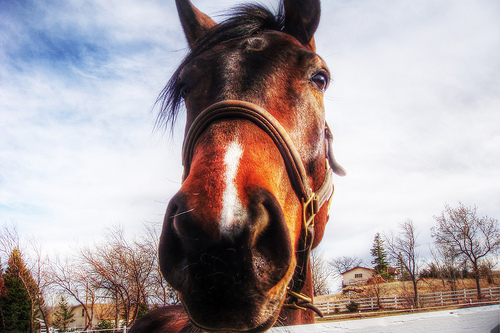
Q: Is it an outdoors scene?
A: Yes, it is outdoors.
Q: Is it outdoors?
A: Yes, it is outdoors.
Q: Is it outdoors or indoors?
A: It is outdoors.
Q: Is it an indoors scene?
A: No, it is outdoors.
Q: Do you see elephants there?
A: No, there are no elephants.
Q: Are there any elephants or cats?
A: No, there are no elephants or cats.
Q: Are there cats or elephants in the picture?
A: No, there are no elephants or cats.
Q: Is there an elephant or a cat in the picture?
A: No, there are no elephants or cats.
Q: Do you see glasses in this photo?
A: No, there are no glasses.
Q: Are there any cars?
A: No, there are no cars.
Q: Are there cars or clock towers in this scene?
A: No, there are no cars or clock towers.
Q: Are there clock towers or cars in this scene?
A: No, there are no cars or clock towers.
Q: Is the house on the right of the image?
A: Yes, the house is on the right of the image.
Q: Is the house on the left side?
A: No, the house is on the right of the image.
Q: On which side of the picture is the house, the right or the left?
A: The house is on the right of the image.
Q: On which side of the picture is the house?
A: The house is on the right of the image.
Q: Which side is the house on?
A: The house is on the right of the image.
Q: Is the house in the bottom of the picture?
A: Yes, the house is in the bottom of the image.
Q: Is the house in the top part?
A: No, the house is in the bottom of the image.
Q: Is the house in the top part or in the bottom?
A: The house is in the bottom of the image.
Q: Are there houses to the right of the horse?
A: Yes, there is a house to the right of the horse.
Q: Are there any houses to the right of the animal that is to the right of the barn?
A: Yes, there is a house to the right of the horse.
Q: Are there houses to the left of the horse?
A: No, the house is to the right of the horse.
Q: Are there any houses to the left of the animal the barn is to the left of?
A: No, the house is to the right of the horse.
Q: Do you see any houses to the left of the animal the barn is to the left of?
A: No, the house is to the right of the horse.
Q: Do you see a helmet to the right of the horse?
A: No, there is a house to the right of the horse.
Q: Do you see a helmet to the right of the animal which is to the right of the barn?
A: No, there is a house to the right of the horse.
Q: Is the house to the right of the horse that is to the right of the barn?
A: Yes, the house is to the right of the horse.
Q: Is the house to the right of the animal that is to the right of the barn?
A: Yes, the house is to the right of the horse.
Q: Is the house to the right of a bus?
A: No, the house is to the right of the horse.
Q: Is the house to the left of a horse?
A: No, the house is to the right of a horse.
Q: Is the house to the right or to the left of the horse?
A: The house is to the right of the horse.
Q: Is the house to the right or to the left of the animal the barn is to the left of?
A: The house is to the right of the horse.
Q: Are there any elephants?
A: No, there are no elephants.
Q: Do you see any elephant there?
A: No, there are no elephants.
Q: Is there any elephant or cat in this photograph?
A: No, there are no elephants or cats.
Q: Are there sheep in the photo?
A: No, there are no sheep.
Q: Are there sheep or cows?
A: No, there are no sheep or cows.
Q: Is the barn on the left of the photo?
A: Yes, the barn is on the left of the image.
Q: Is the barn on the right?
A: No, the barn is on the left of the image.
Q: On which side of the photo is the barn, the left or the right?
A: The barn is on the left of the image.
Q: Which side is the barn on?
A: The barn is on the left of the image.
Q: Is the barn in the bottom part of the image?
A: Yes, the barn is in the bottom of the image.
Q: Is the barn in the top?
A: No, the barn is in the bottom of the image.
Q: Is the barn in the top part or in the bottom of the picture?
A: The barn is in the bottom of the image.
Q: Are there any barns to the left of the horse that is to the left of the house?
A: Yes, there is a barn to the left of the horse.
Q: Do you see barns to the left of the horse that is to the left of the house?
A: Yes, there is a barn to the left of the horse.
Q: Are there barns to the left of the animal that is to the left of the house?
A: Yes, there is a barn to the left of the horse.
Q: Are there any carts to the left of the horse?
A: No, there is a barn to the left of the horse.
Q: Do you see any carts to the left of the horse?
A: No, there is a barn to the left of the horse.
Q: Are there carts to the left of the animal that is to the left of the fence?
A: No, there is a barn to the left of the horse.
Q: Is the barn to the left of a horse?
A: Yes, the barn is to the left of a horse.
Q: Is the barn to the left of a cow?
A: No, the barn is to the left of a horse.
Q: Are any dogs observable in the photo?
A: No, there are no dogs.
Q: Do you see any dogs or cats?
A: No, there are no dogs or cats.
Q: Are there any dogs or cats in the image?
A: No, there are no dogs or cats.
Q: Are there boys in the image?
A: No, there are no boys.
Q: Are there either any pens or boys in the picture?
A: No, there are no boys or pens.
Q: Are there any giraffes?
A: No, there are no giraffes.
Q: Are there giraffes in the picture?
A: No, there are no giraffes.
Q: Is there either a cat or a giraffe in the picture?
A: No, there are no giraffes or cats.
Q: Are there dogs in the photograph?
A: No, there are no dogs.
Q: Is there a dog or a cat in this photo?
A: No, there are no dogs or cats.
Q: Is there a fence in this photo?
A: Yes, there is a fence.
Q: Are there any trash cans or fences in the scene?
A: Yes, there is a fence.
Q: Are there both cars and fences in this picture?
A: No, there is a fence but no cars.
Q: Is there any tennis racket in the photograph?
A: No, there are no rackets.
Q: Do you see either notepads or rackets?
A: No, there are no rackets or notepads.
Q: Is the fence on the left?
A: No, the fence is on the right of the image.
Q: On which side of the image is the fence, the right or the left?
A: The fence is on the right of the image.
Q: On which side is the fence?
A: The fence is on the right of the image.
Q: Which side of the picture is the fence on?
A: The fence is on the right of the image.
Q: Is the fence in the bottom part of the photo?
A: Yes, the fence is in the bottom of the image.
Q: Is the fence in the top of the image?
A: No, the fence is in the bottom of the image.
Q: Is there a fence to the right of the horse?
A: Yes, there is a fence to the right of the horse.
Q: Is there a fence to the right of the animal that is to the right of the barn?
A: Yes, there is a fence to the right of the horse.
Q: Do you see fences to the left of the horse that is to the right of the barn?
A: No, the fence is to the right of the horse.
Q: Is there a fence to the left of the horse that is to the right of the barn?
A: No, the fence is to the right of the horse.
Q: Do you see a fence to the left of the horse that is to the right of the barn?
A: No, the fence is to the right of the horse.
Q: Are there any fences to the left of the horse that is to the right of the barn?
A: No, the fence is to the right of the horse.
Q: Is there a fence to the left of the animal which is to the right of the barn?
A: No, the fence is to the right of the horse.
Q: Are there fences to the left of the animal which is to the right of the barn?
A: No, the fence is to the right of the horse.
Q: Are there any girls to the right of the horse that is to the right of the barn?
A: No, there is a fence to the right of the horse.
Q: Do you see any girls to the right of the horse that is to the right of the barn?
A: No, there is a fence to the right of the horse.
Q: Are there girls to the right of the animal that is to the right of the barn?
A: No, there is a fence to the right of the horse.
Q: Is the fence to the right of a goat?
A: No, the fence is to the right of a horse.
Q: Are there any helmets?
A: No, there are no helmets.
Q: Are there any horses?
A: Yes, there is a horse.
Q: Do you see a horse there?
A: Yes, there is a horse.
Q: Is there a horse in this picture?
A: Yes, there is a horse.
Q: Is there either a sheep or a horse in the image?
A: Yes, there is a horse.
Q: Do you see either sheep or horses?
A: Yes, there is a horse.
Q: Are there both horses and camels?
A: No, there is a horse but no camels.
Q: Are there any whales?
A: No, there are no whales.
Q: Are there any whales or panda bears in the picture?
A: No, there are no whales or panda bears.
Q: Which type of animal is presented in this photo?
A: The animal is a horse.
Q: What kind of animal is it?
A: The animal is a horse.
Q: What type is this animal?
A: This is a horse.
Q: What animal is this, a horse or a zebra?
A: This is a horse.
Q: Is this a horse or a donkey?
A: This is a horse.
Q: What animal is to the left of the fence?
A: The animal is a horse.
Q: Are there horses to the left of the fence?
A: Yes, there is a horse to the left of the fence.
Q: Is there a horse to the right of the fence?
A: No, the horse is to the left of the fence.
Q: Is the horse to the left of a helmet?
A: No, the horse is to the left of the fence.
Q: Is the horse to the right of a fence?
A: No, the horse is to the left of a fence.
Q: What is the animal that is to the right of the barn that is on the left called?
A: The animal is a horse.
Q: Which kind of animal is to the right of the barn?
A: The animal is a horse.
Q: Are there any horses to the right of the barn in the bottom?
A: Yes, there is a horse to the right of the barn.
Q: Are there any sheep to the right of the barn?
A: No, there is a horse to the right of the barn.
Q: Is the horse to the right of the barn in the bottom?
A: Yes, the horse is to the right of the barn.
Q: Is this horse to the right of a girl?
A: No, the horse is to the right of the barn.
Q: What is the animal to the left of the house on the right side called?
A: The animal is a horse.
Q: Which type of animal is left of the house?
A: The animal is a horse.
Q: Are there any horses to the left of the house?
A: Yes, there is a horse to the left of the house.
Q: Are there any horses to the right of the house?
A: No, the horse is to the left of the house.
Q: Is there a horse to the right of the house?
A: No, the horse is to the left of the house.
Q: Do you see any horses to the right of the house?
A: No, the horse is to the left of the house.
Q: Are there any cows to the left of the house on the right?
A: No, there is a horse to the left of the house.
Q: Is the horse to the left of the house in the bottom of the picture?
A: Yes, the horse is to the left of the house.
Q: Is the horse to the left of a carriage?
A: No, the horse is to the left of the house.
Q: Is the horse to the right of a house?
A: No, the horse is to the left of a house.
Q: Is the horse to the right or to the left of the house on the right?
A: The horse is to the left of the house.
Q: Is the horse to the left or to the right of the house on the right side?
A: The horse is to the left of the house.